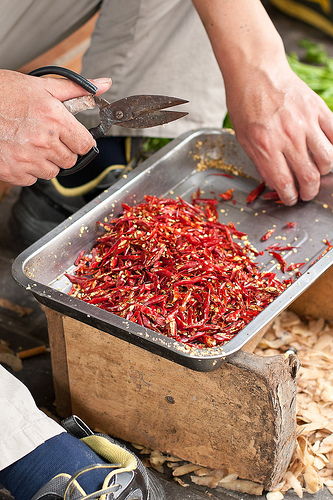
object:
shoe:
[36, 415, 287, 500]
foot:
[69, 449, 109, 489]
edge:
[37, 283, 119, 338]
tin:
[10, 117, 333, 376]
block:
[44, 302, 310, 485]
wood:
[247, 354, 289, 500]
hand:
[226, 68, 333, 207]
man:
[2, 3, 332, 205]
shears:
[25, 61, 190, 183]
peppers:
[268, 248, 288, 274]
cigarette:
[14, 341, 50, 360]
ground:
[32, 366, 53, 397]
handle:
[32, 59, 100, 92]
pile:
[150, 278, 212, 333]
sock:
[14, 432, 99, 493]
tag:
[63, 413, 94, 441]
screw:
[115, 110, 127, 120]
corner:
[184, 135, 246, 184]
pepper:
[246, 179, 271, 206]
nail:
[94, 77, 114, 85]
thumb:
[43, 71, 114, 97]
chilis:
[88, 290, 111, 308]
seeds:
[254, 210, 260, 218]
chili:
[261, 222, 275, 243]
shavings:
[312, 360, 326, 389]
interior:
[94, 449, 128, 467]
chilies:
[146, 289, 168, 305]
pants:
[4, 0, 234, 135]